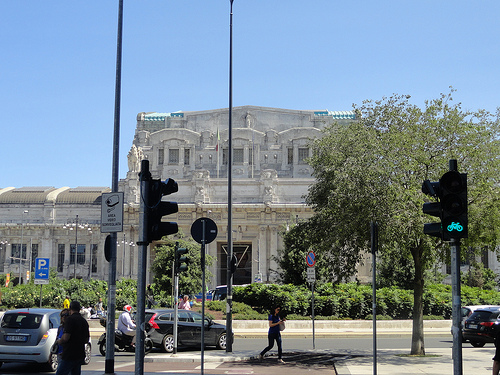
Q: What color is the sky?
A: Blue.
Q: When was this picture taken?
A: Daytime.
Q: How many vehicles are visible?
A: 5.